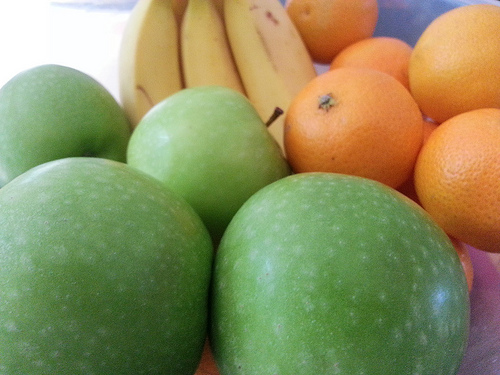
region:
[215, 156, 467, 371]
this this is an apple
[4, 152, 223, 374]
this this is an apple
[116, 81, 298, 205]
this this is an apple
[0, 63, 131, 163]
this this is an apple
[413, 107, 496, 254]
this is an orange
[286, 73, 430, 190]
this is an orange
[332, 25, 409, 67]
this is an orange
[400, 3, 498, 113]
this is an orange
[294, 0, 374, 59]
this is an orange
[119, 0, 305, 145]
a bunch of bananas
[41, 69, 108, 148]
Large green apple near bananas.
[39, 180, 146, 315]
White spots on green apple.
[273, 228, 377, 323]
White spots on green apple.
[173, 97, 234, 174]
White spots on green apple.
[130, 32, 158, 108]
Yellow bananas near apple.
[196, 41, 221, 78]
Yellow banana between other bananas.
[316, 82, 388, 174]
Large orange near apple.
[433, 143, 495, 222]
Large orange near apple.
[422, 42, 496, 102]
Round orange in pile of fruit.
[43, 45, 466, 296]
Fruit sitting on surface.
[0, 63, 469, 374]
The apples are green.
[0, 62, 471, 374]
Four apples are in the picture.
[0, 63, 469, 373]
The apples are clean.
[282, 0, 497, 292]
The oranges are in a pile.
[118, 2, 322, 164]
A group of bananas.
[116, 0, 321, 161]
The bananas are yellow.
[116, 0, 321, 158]
The bananas are ripe.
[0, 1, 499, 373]
A lot of fruit.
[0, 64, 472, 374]
The apples have light spots on them.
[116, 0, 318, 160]
The bananas are long.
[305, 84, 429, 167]
piece of fruit on table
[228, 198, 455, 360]
piece of fruit on table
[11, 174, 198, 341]
piece of fruit on table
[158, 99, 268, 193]
piece of fruit on table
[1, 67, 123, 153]
piece of fruit on table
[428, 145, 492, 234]
piece of fruit on table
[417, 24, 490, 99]
piece of fruit on table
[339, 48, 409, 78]
piece of fruit on table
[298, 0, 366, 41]
piece of fruit on table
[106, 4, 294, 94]
piece of fruit on table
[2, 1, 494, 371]
a close up of some fruit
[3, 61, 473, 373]
a couple of green apples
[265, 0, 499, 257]
some oranges on the right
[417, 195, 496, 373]
a purple table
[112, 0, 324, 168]
a group of yellow bananas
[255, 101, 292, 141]
an apple stem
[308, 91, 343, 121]
an orange stem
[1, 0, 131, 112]
a bright spot in the background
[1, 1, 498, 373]
a handful of fruit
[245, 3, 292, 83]
a bruise spot on a banana